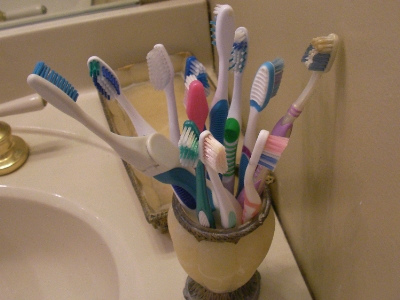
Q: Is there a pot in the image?
A: No, there are no pots.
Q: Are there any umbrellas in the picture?
A: No, there are no umbrellas.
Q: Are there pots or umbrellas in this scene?
A: No, there are no umbrellas or pots.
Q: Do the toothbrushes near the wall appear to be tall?
A: Yes, the toothbrushes are tall.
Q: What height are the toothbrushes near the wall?
A: The toothbrushes are tall.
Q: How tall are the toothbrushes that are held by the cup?
A: The toothbrushes are tall.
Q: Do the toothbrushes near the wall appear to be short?
A: No, the toothbrushes are tall.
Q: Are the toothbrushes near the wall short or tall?
A: The toothbrushes are tall.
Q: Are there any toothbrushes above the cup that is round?
A: Yes, there are toothbrushes above the cup.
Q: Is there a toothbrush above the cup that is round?
A: Yes, there are toothbrushes above the cup.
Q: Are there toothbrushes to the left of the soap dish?
A: Yes, there are toothbrushes to the left of the soap dish.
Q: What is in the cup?
A: The toothbrushes are in the cup.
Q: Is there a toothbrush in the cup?
A: Yes, there are toothbrushes in the cup.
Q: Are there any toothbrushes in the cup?
A: Yes, there are toothbrushes in the cup.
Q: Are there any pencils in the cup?
A: No, there are toothbrushes in the cup.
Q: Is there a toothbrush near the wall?
A: Yes, there are toothbrushes near the wall.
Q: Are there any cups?
A: Yes, there is a cup.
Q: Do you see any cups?
A: Yes, there is a cup.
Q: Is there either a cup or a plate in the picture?
A: Yes, there is a cup.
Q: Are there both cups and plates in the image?
A: No, there is a cup but no plates.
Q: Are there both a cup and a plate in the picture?
A: No, there is a cup but no plates.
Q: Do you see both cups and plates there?
A: No, there is a cup but no plates.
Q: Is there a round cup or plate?
A: Yes, there is a round cup.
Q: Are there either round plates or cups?
A: Yes, there is a round cup.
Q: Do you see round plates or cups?
A: Yes, there is a round cup.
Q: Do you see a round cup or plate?
A: Yes, there is a round cup.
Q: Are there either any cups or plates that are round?
A: Yes, the cup is round.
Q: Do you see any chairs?
A: No, there are no chairs.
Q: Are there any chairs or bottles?
A: No, there are no chairs or bottles.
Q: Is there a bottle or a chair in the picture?
A: No, there are no chairs or bottles.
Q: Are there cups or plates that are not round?
A: No, there is a cup but it is round.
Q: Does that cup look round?
A: Yes, the cup is round.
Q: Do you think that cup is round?
A: Yes, the cup is round.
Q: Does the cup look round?
A: Yes, the cup is round.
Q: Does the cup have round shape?
A: Yes, the cup is round.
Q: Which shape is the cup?
A: The cup is round.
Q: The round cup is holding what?
A: The cup is holding the toothbrushes.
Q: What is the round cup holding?
A: The cup is holding the toothbrushes.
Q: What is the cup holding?
A: The cup is holding the toothbrushes.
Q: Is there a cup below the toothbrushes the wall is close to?
A: Yes, there is a cup below the toothbrushes.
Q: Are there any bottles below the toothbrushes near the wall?
A: No, there is a cup below the toothbrushes.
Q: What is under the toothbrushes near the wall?
A: The cup is under the toothbrushes.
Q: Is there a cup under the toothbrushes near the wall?
A: Yes, there is a cup under the toothbrushes.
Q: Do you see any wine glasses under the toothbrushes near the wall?
A: No, there is a cup under the toothbrushes.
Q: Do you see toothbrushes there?
A: Yes, there is a toothbrush.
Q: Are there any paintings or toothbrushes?
A: Yes, there is a toothbrush.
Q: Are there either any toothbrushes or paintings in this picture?
A: Yes, there is a toothbrush.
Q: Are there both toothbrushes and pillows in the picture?
A: No, there is a toothbrush but no pillows.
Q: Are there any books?
A: No, there are no books.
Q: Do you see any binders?
A: No, there are no binders.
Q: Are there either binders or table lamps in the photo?
A: No, there are no binders or table lamps.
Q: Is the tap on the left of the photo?
A: Yes, the tap is on the left of the image.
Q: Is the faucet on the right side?
A: No, the faucet is on the left of the image.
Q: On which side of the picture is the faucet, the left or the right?
A: The faucet is on the left of the image.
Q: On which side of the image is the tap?
A: The tap is on the left of the image.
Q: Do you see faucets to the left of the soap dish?
A: Yes, there is a faucet to the left of the soap dish.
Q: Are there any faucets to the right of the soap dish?
A: No, the faucet is to the left of the soap dish.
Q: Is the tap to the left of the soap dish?
A: Yes, the tap is to the left of the soap dish.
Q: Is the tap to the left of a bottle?
A: No, the tap is to the left of the soap dish.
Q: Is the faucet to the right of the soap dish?
A: No, the faucet is to the left of the soap dish.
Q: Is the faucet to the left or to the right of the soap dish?
A: The faucet is to the left of the soap dish.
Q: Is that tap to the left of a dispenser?
A: No, the tap is to the left of the toothbrush.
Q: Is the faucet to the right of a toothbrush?
A: No, the faucet is to the left of a toothbrush.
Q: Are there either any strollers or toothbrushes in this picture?
A: Yes, there is a toothbrush.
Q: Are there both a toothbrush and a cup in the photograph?
A: Yes, there are both a toothbrush and a cup.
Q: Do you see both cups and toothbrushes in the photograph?
A: Yes, there are both a toothbrush and a cup.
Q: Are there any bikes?
A: No, there are no bikes.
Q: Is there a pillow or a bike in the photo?
A: No, there are no bikes or pillows.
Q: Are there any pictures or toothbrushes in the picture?
A: Yes, there is a toothbrush.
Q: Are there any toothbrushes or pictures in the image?
A: Yes, there is a toothbrush.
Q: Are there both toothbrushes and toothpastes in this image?
A: No, there is a toothbrush but no toothpastes.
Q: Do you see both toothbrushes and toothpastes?
A: No, there is a toothbrush but no toothpastes.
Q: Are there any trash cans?
A: No, there are no trash cans.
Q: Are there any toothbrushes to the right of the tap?
A: Yes, there is a toothbrush to the right of the tap.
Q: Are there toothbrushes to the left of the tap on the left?
A: No, the toothbrush is to the right of the tap.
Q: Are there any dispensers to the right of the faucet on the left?
A: No, there is a toothbrush to the right of the faucet.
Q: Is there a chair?
A: No, there are no chairs.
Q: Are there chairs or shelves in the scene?
A: No, there are no chairs or shelves.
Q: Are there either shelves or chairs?
A: No, there are no chairs or shelves.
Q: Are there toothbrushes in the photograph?
A: Yes, there is a toothbrush.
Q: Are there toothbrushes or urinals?
A: Yes, there is a toothbrush.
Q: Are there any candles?
A: No, there are no candles.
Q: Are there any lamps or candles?
A: No, there are no candles or lamps.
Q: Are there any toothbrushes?
A: Yes, there is a toothbrush.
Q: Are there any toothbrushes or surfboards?
A: Yes, there is a toothbrush.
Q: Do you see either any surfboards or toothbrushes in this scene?
A: Yes, there is a toothbrush.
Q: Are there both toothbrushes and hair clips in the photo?
A: No, there is a toothbrush but no hair clips.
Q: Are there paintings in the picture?
A: No, there are no paintings.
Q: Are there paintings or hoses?
A: No, there are no paintings or hoses.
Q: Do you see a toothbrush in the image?
A: Yes, there is a toothbrush.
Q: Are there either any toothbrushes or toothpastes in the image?
A: Yes, there is a toothbrush.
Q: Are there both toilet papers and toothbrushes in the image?
A: No, there is a toothbrush but no toilet papers.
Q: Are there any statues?
A: No, there are no statues.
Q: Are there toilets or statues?
A: No, there are no statues or toilets.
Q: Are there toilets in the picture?
A: No, there are no toilets.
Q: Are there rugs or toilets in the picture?
A: No, there are no toilets or rugs.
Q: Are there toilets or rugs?
A: No, there are no toilets or rugs.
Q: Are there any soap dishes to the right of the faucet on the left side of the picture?
A: Yes, there is a soap dish to the right of the tap.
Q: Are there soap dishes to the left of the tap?
A: No, the soap dish is to the right of the tap.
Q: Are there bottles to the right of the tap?
A: No, there is a soap dish to the right of the tap.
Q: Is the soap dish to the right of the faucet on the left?
A: Yes, the soap dish is to the right of the faucet.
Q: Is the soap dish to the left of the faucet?
A: No, the soap dish is to the right of the faucet.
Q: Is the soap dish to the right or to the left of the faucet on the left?
A: The soap dish is to the right of the tap.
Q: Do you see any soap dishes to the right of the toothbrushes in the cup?
A: Yes, there is a soap dish to the right of the toothbrushes.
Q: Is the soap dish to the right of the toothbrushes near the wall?
A: Yes, the soap dish is to the right of the toothbrushes.